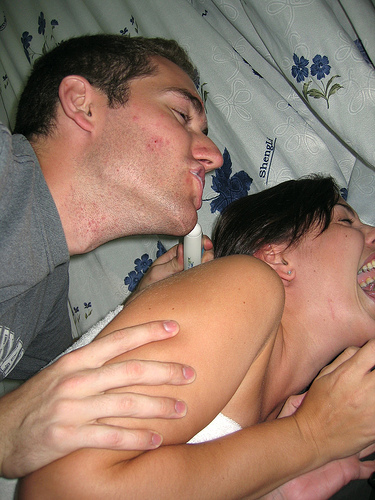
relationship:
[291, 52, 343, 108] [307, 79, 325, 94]
design on stems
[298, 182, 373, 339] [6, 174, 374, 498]
face of woman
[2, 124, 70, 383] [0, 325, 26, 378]
shirt with logo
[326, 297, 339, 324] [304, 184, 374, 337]
scratch on face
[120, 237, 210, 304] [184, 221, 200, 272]
hand holds toothbrush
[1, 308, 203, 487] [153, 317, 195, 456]
hand has fingernails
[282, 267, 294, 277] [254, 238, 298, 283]
earring in ear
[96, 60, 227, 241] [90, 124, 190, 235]
face has razor stubble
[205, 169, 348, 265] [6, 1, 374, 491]
hair on bed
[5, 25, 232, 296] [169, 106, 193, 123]
man has eye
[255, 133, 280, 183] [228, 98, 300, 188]
words on bedsheet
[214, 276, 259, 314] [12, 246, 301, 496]
freckles on arm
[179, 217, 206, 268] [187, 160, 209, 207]
toothbrush in mouth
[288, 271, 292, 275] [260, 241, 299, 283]
earring in ear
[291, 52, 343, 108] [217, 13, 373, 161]
design on sheet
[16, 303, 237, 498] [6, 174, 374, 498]
towel around woman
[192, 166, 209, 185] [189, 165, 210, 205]
foam in mouth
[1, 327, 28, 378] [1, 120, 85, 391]
logo on shirt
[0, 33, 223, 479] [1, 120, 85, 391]
man has shirt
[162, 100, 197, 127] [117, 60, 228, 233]
eye on face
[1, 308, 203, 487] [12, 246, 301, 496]
hand on arm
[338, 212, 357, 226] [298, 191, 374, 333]
eye on face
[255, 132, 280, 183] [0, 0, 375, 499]
words on bed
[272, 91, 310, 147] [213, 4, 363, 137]
design on sheet